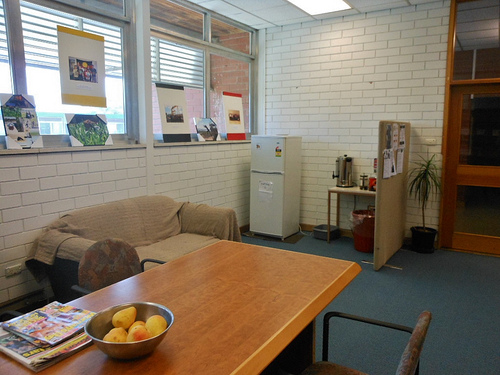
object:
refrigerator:
[250, 134, 303, 241]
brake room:
[0, 1, 498, 375]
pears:
[102, 307, 166, 343]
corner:
[249, 23, 296, 131]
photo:
[0, 93, 44, 150]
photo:
[65, 113, 114, 147]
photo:
[154, 83, 192, 144]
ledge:
[153, 140, 251, 148]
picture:
[56, 24, 107, 108]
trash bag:
[350, 209, 375, 253]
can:
[351, 208, 375, 252]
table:
[328, 185, 376, 244]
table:
[2, 239, 361, 375]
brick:
[291, 102, 309, 108]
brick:
[310, 40, 331, 48]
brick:
[400, 45, 426, 54]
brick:
[375, 31, 401, 41]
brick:
[364, 41, 388, 50]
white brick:
[330, 98, 352, 107]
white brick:
[300, 107, 319, 114]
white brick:
[272, 73, 292, 81]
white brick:
[272, 102, 290, 109]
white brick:
[410, 85, 438, 96]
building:
[0, 4, 449, 269]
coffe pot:
[332, 154, 354, 188]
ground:
[381, 263, 499, 318]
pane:
[457, 93, 500, 168]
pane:
[452, 184, 500, 237]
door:
[438, 81, 500, 257]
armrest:
[322, 310, 413, 362]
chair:
[298, 311, 431, 375]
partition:
[373, 120, 410, 270]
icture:
[65, 113, 114, 147]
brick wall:
[255, 0, 451, 242]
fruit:
[102, 306, 167, 343]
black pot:
[410, 226, 437, 254]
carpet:
[400, 274, 475, 311]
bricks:
[318, 135, 339, 143]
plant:
[401, 152, 449, 232]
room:
[0, 2, 496, 371]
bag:
[348, 209, 374, 237]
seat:
[24, 195, 241, 304]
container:
[333, 154, 354, 188]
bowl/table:
[85, 300, 172, 361]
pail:
[351, 208, 376, 252]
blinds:
[0, 0, 139, 141]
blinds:
[151, 37, 206, 88]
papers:
[0, 300, 94, 375]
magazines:
[0, 300, 96, 372]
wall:
[2, 150, 246, 211]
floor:
[343, 242, 481, 365]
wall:
[270, 25, 439, 225]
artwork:
[68, 57, 97, 84]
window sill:
[0, 140, 144, 158]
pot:
[410, 226, 438, 253]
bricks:
[349, 113, 373, 121]